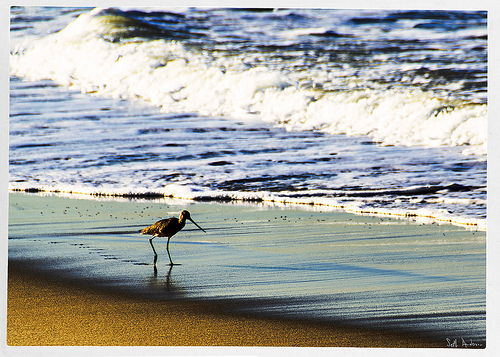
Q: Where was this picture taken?
A: On a beach.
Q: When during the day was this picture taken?
A: Daytime.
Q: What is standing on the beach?
A: A bird.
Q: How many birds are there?
A: One.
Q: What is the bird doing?
A: Standing on the beach.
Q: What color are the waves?
A: White.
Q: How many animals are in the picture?
A: One.